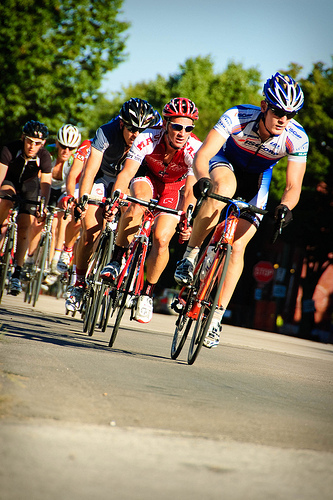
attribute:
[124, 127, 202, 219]
outfit — red, white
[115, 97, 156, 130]
helmet — black, white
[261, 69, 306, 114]
helmet — blue, white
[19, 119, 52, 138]
helmet — black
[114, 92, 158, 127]
helmet — black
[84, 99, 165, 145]
outfit — black, white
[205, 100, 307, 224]
blue/white outfit — white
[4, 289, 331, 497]
road — light grey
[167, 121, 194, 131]
sunglasses — white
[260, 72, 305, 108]
helmet — red, grey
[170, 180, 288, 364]
bike — orange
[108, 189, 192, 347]
bike — orange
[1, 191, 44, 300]
bike — orange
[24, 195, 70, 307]
bike — orange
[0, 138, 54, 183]
shirt — black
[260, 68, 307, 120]
helmet — blue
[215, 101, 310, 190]
shirt — black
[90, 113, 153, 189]
shirt — black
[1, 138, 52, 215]
shirt — black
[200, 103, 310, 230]
outfit — blue